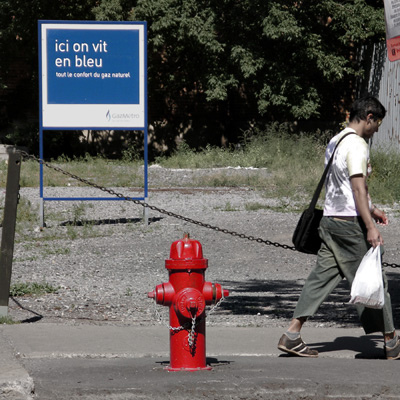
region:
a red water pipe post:
[45, 139, 253, 360]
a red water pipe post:
[145, 230, 227, 392]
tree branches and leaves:
[161, 7, 317, 116]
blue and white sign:
[29, 12, 154, 228]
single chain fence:
[206, 213, 279, 249]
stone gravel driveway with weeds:
[56, 202, 144, 295]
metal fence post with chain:
[0, 149, 60, 317]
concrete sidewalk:
[8, 324, 161, 360]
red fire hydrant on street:
[138, 216, 230, 384]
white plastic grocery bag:
[340, 226, 394, 334]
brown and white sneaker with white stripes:
[270, 320, 316, 364]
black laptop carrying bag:
[286, 125, 360, 264]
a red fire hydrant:
[131, 217, 250, 379]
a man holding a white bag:
[326, 93, 387, 311]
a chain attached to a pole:
[0, 145, 305, 245]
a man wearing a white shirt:
[315, 79, 387, 234]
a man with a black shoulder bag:
[300, 109, 381, 261]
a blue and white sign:
[25, 17, 161, 205]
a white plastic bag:
[343, 233, 384, 315]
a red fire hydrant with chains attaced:
[148, 232, 235, 372]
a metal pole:
[0, 134, 31, 295]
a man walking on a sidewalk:
[247, 106, 384, 387]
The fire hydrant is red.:
[145, 226, 229, 379]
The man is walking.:
[274, 83, 399, 359]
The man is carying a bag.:
[267, 89, 399, 361]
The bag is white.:
[340, 228, 393, 314]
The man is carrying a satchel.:
[275, 86, 399, 262]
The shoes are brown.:
[258, 308, 398, 369]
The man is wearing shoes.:
[267, 70, 399, 362]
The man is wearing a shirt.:
[286, 91, 391, 229]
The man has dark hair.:
[338, 89, 389, 136]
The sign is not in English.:
[32, 15, 158, 235]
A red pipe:
[156, 237, 252, 390]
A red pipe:
[145, 195, 225, 372]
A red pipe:
[161, 274, 219, 396]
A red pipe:
[163, 243, 213, 355]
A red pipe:
[176, 211, 243, 392]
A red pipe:
[154, 243, 214, 395]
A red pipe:
[148, 204, 215, 386]